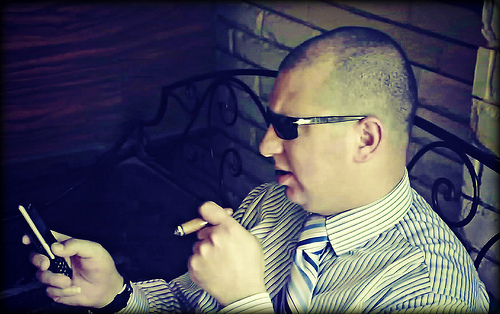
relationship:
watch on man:
[108, 253, 142, 311] [68, 21, 492, 296]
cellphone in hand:
[9, 195, 76, 285] [8, 221, 135, 311]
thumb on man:
[50, 224, 114, 276] [11, 13, 497, 309]